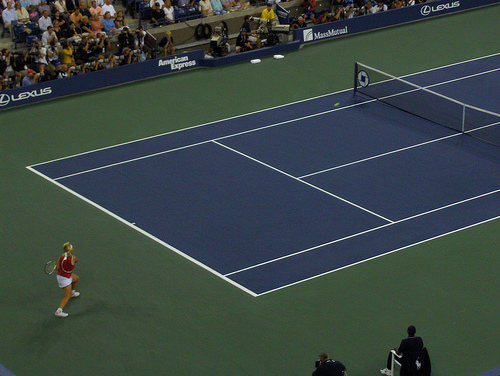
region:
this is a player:
[40, 234, 109, 319]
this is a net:
[348, 36, 499, 153]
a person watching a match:
[46, 56, 73, 80]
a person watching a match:
[386, 311, 431, 371]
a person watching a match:
[112, 28, 154, 55]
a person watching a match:
[88, 19, 114, 56]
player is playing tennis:
[17, 222, 92, 323]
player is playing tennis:
[22, 222, 92, 333]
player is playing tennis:
[29, 228, 100, 347]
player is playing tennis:
[29, 229, 98, 342]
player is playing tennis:
[37, 227, 104, 347]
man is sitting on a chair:
[381, 321, 424, 374]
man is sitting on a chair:
[382, 325, 424, 370]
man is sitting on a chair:
[384, 313, 427, 372]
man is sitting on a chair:
[373, 318, 425, 373]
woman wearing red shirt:
[51, 250, 85, 285]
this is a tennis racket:
[34, 252, 75, 283]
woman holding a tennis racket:
[26, 223, 107, 349]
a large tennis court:
[19, 23, 498, 369]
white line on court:
[205, 115, 410, 240]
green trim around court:
[2, 7, 498, 361]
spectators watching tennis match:
[10, 0, 379, 112]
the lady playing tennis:
[43, 240, 80, 318]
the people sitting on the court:
[313, 322, 430, 372]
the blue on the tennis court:
[25, 50, 499, 297]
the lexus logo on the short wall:
[418, 3, 431, 15]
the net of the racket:
[44, 257, 56, 275]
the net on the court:
[350, 58, 499, 144]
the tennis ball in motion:
[333, 100, 341, 107]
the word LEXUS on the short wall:
[8, 86, 53, 100]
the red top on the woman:
[55, 253, 74, 278]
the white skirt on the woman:
[58, 272, 75, 288]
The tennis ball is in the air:
[331, 99, 344, 113]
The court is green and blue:
[73, 107, 278, 233]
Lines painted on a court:
[224, 253, 281, 306]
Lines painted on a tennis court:
[222, 238, 290, 310]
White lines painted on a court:
[223, 248, 303, 324]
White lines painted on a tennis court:
[218, 248, 291, 310]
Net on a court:
[349, 53, 469, 126]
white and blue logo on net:
[352, 69, 370, 95]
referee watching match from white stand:
[387, 322, 429, 374]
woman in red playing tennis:
[43, 239, 84, 324]